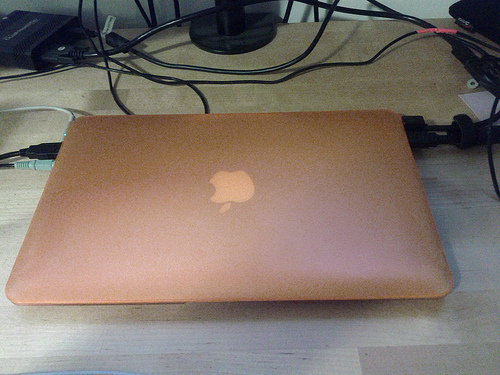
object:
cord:
[93, 0, 211, 116]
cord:
[84, 0, 461, 61]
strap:
[446, 112, 478, 150]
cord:
[438, 125, 499, 146]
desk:
[0, 17, 500, 375]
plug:
[14, 159, 55, 171]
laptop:
[6, 109, 456, 306]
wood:
[170, 331, 372, 373]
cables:
[73, 28, 500, 86]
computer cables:
[425, 109, 500, 132]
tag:
[99, 14, 117, 39]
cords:
[6, 104, 75, 142]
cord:
[93, 0, 340, 76]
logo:
[208, 169, 256, 215]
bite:
[208, 181, 217, 201]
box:
[0, 9, 85, 72]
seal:
[416, 28, 458, 35]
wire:
[79, 21, 499, 84]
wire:
[0, 159, 55, 170]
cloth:
[0, 17, 499, 372]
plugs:
[405, 129, 441, 149]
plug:
[19, 142, 62, 161]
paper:
[458, 90, 500, 121]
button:
[466, 78, 480, 90]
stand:
[187, 2, 280, 56]